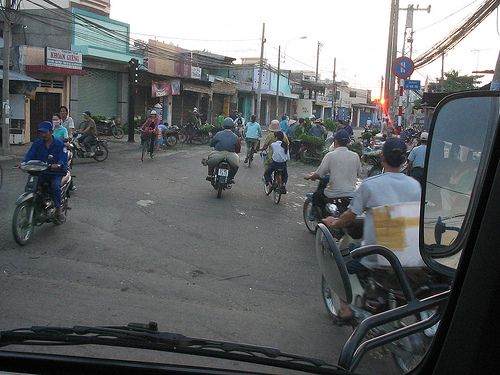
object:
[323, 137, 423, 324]
people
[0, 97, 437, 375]
street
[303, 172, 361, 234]
mopeds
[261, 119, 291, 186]
person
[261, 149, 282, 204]
bicycle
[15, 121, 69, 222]
man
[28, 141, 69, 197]
blue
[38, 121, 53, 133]
hat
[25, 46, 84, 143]
storefronts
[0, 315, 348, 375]
wiper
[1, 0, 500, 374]
window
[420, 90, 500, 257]
mirror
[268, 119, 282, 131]
hat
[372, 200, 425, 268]
bag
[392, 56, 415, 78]
sign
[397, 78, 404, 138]
pole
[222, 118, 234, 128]
helmet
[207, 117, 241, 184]
bicyclist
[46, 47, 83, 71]
sign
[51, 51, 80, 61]
letters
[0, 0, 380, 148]
building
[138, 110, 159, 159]
woman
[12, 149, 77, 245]
moped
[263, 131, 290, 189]
person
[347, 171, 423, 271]
shirt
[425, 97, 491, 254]
reflection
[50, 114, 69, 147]
woman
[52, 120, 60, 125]
mask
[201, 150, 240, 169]
luggage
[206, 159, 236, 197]
moped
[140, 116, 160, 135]
shirt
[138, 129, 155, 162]
bicycle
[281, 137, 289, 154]
ponytail